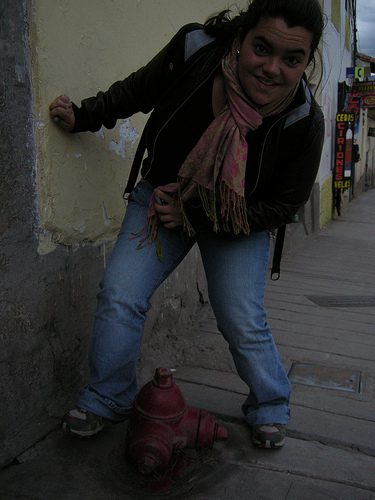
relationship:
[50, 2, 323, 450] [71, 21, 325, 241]
lady wearing a black jacket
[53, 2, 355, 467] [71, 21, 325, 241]
lady wearing a black jacket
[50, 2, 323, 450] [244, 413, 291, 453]
lady wearing shoe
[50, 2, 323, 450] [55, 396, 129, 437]
lady wearing shoe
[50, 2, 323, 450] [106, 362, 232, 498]
lady near a fire hydrant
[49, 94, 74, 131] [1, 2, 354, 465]
hand on a wall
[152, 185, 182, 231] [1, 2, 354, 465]
hand on a wall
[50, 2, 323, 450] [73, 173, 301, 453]
lady wearing jeans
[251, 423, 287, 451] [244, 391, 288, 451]
shoe on foot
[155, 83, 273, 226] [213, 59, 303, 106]
scarf around woman's neck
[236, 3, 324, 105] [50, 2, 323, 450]
face of lady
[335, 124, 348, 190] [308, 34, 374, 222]
sign in background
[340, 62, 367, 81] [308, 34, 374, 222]
sign in background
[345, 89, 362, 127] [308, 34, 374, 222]
sign in background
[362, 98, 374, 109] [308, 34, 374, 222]
sign in background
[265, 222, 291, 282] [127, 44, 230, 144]
strap on backpack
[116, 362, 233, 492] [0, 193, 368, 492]
fire hydrant on ground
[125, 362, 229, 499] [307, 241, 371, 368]
fire hydrant on ground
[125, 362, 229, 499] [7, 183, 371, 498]
fire hydrant on sidewalk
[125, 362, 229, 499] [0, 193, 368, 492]
fire hydrant on ground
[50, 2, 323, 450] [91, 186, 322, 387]
lady wearing blue jeans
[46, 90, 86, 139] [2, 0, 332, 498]
hand against wall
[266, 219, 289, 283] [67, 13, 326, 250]
buckle hanging off jacket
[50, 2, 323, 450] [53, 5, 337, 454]
lady wears jeans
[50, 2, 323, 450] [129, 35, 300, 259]
lady wearing a scarf